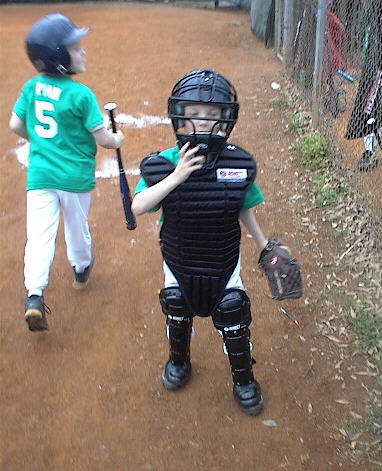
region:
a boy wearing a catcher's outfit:
[124, 57, 309, 422]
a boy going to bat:
[7, 11, 137, 336]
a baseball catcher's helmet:
[166, 64, 234, 178]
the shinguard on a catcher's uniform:
[219, 327, 263, 387]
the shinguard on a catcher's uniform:
[156, 316, 200, 361]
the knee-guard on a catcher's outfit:
[208, 294, 251, 328]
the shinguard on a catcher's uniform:
[152, 282, 198, 326]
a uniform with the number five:
[5, 69, 122, 198]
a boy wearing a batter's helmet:
[19, 12, 91, 84]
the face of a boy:
[181, 102, 224, 139]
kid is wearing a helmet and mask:
[141, 55, 251, 180]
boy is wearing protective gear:
[112, 68, 298, 429]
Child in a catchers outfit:
[130, 64, 301, 399]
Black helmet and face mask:
[164, 73, 239, 170]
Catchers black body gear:
[157, 158, 246, 297]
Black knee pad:
[217, 290, 244, 329]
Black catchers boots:
[220, 329, 262, 414]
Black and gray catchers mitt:
[265, 228, 309, 321]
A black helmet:
[22, 9, 94, 72]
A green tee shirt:
[22, 66, 106, 195]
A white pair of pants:
[26, 191, 95, 297]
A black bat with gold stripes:
[103, 90, 136, 236]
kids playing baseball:
[16, 14, 380, 400]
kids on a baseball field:
[22, 8, 331, 398]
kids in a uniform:
[17, 7, 355, 379]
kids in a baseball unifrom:
[25, 35, 319, 358]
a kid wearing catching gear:
[118, 39, 371, 399]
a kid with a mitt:
[151, 66, 380, 426]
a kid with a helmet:
[12, 12, 78, 106]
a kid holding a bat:
[2, 17, 226, 390]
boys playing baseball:
[27, 31, 368, 384]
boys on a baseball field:
[16, 17, 294, 391]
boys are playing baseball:
[7, 11, 376, 362]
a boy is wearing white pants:
[37, 229, 44, 279]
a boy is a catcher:
[142, 91, 286, 413]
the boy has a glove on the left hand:
[259, 247, 304, 301]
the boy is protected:
[149, 150, 266, 438]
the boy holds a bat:
[99, 97, 160, 272]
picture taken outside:
[0, 88, 366, 462]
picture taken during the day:
[7, 96, 378, 452]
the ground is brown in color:
[80, 334, 118, 442]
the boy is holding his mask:
[159, 88, 234, 179]